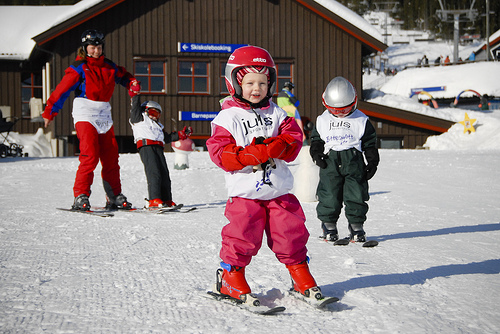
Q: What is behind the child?
A: Brown building.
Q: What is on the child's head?
A: A helmet.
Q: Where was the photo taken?
A: Outside somewhere.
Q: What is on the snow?
A: Shadows.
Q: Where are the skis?
A: On the feet.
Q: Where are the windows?
A: On the building.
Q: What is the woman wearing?
A: Blue and red coat.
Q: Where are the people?
A: In the snow.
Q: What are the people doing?
A: Skiing.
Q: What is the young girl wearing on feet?
A: Snowshoes.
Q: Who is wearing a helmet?
A: A young girl.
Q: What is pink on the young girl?
A: Pants.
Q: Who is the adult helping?
A: A child.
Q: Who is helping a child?
A: A woman.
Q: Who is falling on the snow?
A: A child.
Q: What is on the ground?
A: White snow.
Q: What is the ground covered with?
A: Snow.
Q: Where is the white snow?
A: On the ground.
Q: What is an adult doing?
A: Holding up a child.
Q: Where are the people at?
A: Ski resort.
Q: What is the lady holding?
A: Kid's hand.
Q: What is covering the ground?
A: Snow.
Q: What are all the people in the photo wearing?
A: Snowsuits.